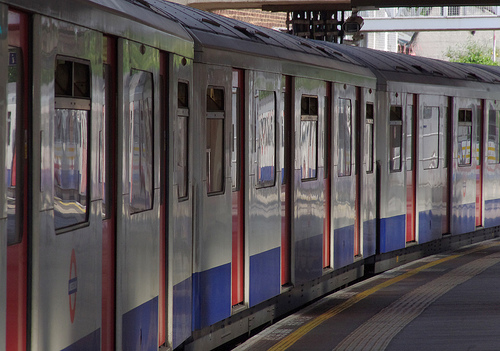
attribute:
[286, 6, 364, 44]
equipment — metal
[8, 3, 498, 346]
train — blue, silver, old, red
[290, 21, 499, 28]
support beam — white, metal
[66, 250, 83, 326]
logo — red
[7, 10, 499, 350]
doors — red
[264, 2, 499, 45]
beam — metal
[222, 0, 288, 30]
building — brick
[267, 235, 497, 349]
stripe — yellow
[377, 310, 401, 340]
brick — white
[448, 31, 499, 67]
tree — green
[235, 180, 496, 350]
line — yellow, black, curved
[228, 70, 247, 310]
door — red